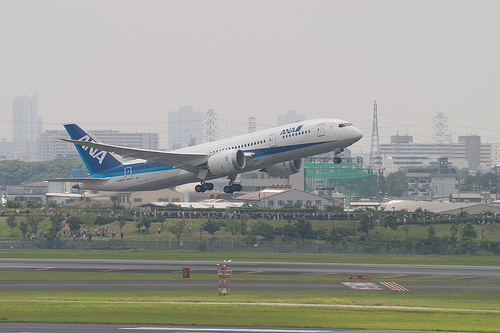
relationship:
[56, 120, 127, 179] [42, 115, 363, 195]
tail of jet plane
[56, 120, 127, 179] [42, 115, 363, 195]
tail on jet plane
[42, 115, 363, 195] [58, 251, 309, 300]
jet plane near runway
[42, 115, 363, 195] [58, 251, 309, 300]
jet plane above runway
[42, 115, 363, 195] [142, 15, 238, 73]
jet plane in sky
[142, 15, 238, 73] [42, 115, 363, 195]
sky above jet plane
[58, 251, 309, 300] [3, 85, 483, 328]
runway at airport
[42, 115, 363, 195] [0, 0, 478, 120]
jet plane going in sky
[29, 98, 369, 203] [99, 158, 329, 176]
jet plane with stripe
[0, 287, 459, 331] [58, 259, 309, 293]
grass between runway